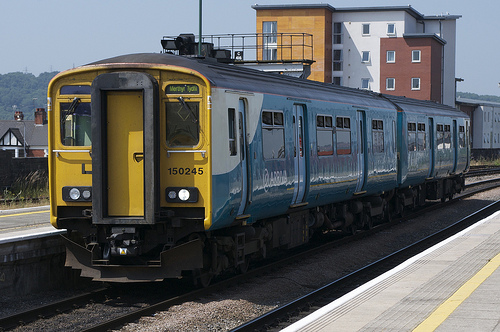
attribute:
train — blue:
[59, 74, 452, 225]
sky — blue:
[40, 12, 84, 43]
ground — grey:
[389, 283, 455, 330]